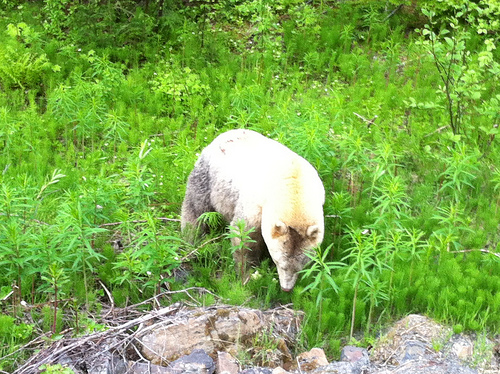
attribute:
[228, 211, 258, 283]
leg — bear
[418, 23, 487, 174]
plant — part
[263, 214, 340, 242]
ear — bear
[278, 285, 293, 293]
nose — bear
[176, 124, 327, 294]
bear — white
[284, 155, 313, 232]
stripe — red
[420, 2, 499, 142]
tree — young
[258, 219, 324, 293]
head — part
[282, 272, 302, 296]
nose — part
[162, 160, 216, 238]
leg — back, bear